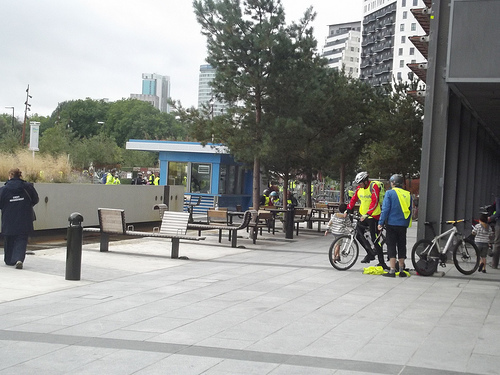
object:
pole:
[171, 238, 179, 259]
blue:
[165, 154, 216, 161]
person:
[471, 214, 493, 273]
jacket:
[101, 172, 114, 185]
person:
[324, 203, 352, 261]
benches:
[153, 204, 252, 231]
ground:
[4, 282, 500, 375]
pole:
[100, 232, 109, 252]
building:
[359, 0, 427, 121]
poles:
[21, 84, 33, 146]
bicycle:
[411, 219, 481, 277]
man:
[343, 171, 388, 269]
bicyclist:
[328, 209, 390, 270]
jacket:
[347, 181, 382, 221]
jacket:
[378, 187, 413, 228]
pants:
[386, 225, 407, 259]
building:
[195, 63, 239, 114]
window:
[190, 162, 213, 194]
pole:
[65, 212, 83, 281]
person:
[0, 168, 39, 269]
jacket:
[0, 178, 39, 236]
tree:
[190, 0, 295, 222]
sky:
[0, 0, 186, 68]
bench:
[81, 227, 206, 241]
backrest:
[97, 208, 126, 235]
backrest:
[159, 211, 190, 236]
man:
[377, 174, 412, 278]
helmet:
[354, 171, 369, 184]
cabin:
[125, 138, 271, 216]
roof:
[125, 138, 231, 154]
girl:
[472, 214, 495, 273]